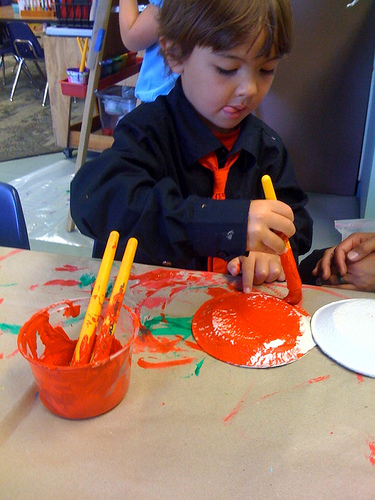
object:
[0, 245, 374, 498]
table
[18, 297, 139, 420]
paint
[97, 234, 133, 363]
brush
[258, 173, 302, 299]
brush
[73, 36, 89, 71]
brush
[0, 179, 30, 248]
chair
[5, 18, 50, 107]
chair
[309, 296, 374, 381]
plate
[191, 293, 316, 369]
plate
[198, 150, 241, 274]
tie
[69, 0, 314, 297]
child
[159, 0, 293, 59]
hair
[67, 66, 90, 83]
container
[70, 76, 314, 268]
shirt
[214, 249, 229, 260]
button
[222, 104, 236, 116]
tongue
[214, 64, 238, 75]
eyelashes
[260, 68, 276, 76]
eyelashes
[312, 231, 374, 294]
hands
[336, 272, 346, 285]
ring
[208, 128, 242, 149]
shirt